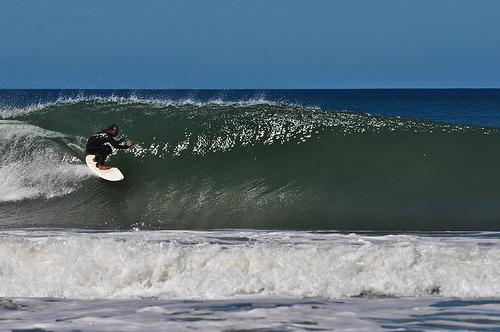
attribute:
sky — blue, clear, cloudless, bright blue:
[4, 8, 495, 88]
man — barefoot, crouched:
[72, 120, 125, 162]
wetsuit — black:
[81, 131, 119, 159]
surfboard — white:
[83, 152, 124, 183]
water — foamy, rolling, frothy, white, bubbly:
[3, 89, 493, 331]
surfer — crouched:
[79, 115, 132, 170]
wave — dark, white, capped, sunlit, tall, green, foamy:
[21, 98, 311, 155]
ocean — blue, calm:
[2, 86, 499, 330]